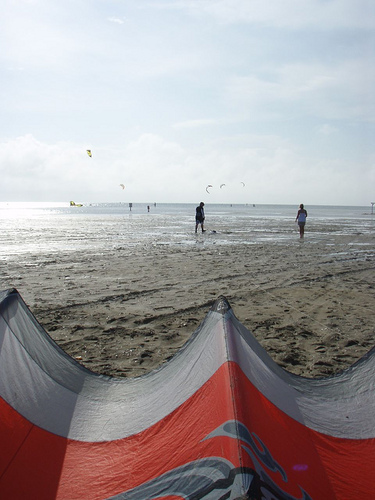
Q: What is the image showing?
A: It is showing a beach.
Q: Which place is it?
A: It is a beach.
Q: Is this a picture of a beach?
A: Yes, it is showing a beach.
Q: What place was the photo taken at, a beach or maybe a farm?
A: It was taken at a beach.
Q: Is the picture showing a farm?
A: No, the picture is showing a beach.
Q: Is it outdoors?
A: Yes, it is outdoors.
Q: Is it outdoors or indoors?
A: It is outdoors.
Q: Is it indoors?
A: No, it is outdoors.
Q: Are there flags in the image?
A: No, there are no flags.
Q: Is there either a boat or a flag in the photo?
A: No, there are no flags or boats.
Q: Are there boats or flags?
A: No, there are no flags or boats.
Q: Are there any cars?
A: No, there are no cars.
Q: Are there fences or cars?
A: No, there are no cars or fences.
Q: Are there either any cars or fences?
A: No, there are no cars or fences.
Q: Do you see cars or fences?
A: No, there are no cars or fences.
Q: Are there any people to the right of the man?
A: Yes, there are people to the right of the man.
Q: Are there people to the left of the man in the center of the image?
A: No, the people are to the right of the man.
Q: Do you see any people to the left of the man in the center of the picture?
A: No, the people are to the right of the man.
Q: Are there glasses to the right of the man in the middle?
A: No, there are people to the right of the man.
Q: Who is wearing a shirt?
A: The people are wearing a shirt.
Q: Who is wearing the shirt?
A: The people are wearing a shirt.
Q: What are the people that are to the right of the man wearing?
A: The people are wearing a shirt.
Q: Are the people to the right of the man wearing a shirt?
A: Yes, the people are wearing a shirt.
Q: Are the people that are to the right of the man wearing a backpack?
A: No, the people are wearing a shirt.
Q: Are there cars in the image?
A: No, there are no cars.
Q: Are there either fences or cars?
A: No, there are no cars or fences.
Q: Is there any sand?
A: Yes, there is sand.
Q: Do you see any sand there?
A: Yes, there is sand.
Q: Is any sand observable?
A: Yes, there is sand.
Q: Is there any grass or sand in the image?
A: Yes, there is sand.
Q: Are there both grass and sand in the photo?
A: No, there is sand but no grass.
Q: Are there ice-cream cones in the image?
A: No, there are no ice-cream cones.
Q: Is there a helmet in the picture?
A: No, there are no helmets.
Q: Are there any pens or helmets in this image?
A: No, there are no helmets or pens.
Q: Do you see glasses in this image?
A: No, there are no glasses.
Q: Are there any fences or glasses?
A: No, there are no glasses or fences.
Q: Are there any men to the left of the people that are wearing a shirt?
A: Yes, there is a man to the left of the people.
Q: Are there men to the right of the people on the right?
A: No, the man is to the left of the people.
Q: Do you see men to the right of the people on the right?
A: No, the man is to the left of the people.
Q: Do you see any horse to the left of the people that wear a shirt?
A: No, there is a man to the left of the people.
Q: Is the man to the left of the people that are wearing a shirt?
A: Yes, the man is to the left of the people.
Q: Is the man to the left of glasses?
A: No, the man is to the left of the people.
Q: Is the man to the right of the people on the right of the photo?
A: No, the man is to the left of the people.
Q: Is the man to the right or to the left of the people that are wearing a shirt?
A: The man is to the left of the people.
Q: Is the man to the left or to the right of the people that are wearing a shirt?
A: The man is to the left of the people.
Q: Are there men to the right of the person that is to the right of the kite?
A: Yes, there is a man to the right of the person.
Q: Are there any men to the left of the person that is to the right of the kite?
A: No, the man is to the right of the person.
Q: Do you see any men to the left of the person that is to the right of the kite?
A: No, the man is to the right of the person.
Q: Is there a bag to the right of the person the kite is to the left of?
A: No, there is a man to the right of the person.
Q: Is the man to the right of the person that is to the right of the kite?
A: Yes, the man is to the right of the person.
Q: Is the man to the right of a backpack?
A: No, the man is to the right of the person.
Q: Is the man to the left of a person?
A: No, the man is to the right of a person.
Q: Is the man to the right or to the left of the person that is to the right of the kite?
A: The man is to the right of the person.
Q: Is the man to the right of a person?
A: Yes, the man is to the right of a person.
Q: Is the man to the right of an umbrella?
A: No, the man is to the right of a person.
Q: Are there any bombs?
A: No, there are no bombs.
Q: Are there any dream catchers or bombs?
A: No, there are no bombs or dream catchers.